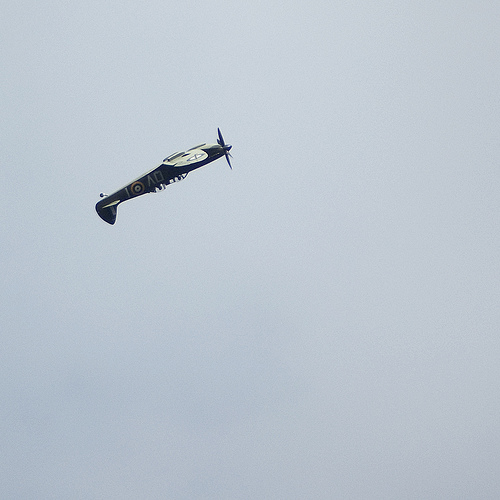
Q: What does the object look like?
A: A Jet or Plane.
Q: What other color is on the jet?
A: White.